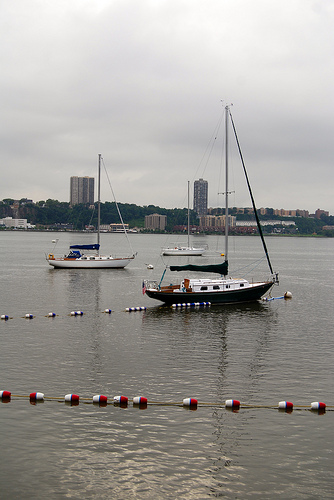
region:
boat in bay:
[135, 263, 277, 303]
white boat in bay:
[32, 242, 135, 280]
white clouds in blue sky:
[28, 8, 78, 50]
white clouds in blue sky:
[96, 17, 144, 53]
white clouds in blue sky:
[19, 65, 64, 100]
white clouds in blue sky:
[133, 170, 165, 195]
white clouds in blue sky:
[266, 79, 324, 130]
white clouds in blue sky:
[100, 84, 153, 132]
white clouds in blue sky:
[116, 21, 166, 86]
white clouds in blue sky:
[63, 102, 91, 124]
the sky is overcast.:
[4, 5, 332, 201]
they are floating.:
[1, 381, 320, 435]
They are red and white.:
[4, 387, 324, 418]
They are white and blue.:
[0, 299, 214, 318]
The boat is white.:
[141, 250, 279, 327]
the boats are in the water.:
[42, 233, 248, 321]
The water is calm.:
[5, 232, 331, 484]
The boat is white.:
[42, 243, 134, 275]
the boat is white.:
[157, 240, 204, 262]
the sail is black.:
[166, 261, 233, 277]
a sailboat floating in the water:
[144, 106, 270, 302]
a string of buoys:
[1, 391, 331, 412]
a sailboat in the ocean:
[46, 157, 132, 270]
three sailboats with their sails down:
[48, 101, 275, 301]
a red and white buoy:
[223, 399, 238, 410]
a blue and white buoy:
[103, 304, 114, 314]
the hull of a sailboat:
[139, 282, 282, 302]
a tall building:
[68, 174, 94, 207]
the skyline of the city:
[0, 180, 333, 232]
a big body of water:
[0, 231, 333, 498]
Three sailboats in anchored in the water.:
[26, 118, 303, 346]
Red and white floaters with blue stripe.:
[2, 378, 327, 419]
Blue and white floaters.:
[3, 301, 294, 326]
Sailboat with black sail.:
[141, 239, 295, 318]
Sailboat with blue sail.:
[45, 220, 143, 276]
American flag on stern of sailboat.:
[136, 275, 154, 297]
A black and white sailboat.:
[141, 98, 285, 307]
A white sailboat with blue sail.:
[43, 150, 139, 275]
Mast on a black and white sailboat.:
[139, 103, 282, 311]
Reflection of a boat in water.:
[164, 308, 268, 465]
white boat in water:
[31, 216, 131, 280]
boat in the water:
[140, 268, 282, 318]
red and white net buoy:
[41, 376, 301, 421]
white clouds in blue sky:
[22, 27, 79, 53]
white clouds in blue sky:
[144, 47, 184, 98]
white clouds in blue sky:
[250, 82, 299, 116]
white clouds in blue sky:
[263, 103, 303, 146]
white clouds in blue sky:
[84, 106, 135, 134]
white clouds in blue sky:
[126, 45, 198, 74]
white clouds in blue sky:
[7, 97, 40, 124]